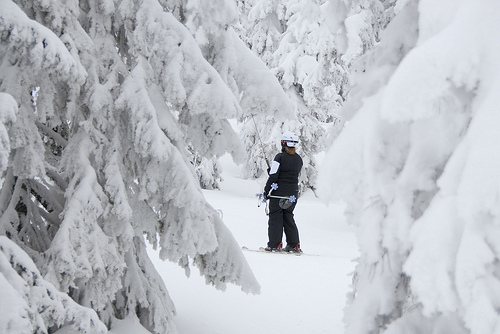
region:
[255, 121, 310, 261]
man with goggles on back of head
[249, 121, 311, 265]
person with goggles on back of head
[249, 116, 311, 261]
guy with goggles on back of head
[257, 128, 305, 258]
man with goggles on head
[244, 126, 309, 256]
person with goggles on head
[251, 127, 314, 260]
guy with goggles on head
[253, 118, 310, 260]
man standing on snow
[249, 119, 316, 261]
man in white hat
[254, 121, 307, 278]
person in white hat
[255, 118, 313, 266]
guy in white hat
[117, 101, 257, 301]
Snow-covered evergreen branch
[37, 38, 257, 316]
Snow-covered trees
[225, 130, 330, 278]
Cross-country skier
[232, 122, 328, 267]
Cross-country skier not using his poles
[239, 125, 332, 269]
Cross-country skier in the snow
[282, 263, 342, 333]
Snow on the ground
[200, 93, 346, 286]
Cross-country skier in the forest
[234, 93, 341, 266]
Cross-country skier in the snow-covered forest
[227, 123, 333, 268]
Cross-country skier taking in the scenery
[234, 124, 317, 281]
Snow skier taking a break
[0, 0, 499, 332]
the trees are heavy with snow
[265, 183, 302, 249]
the girl is wearing black pants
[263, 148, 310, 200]
the girl is wearing a black jacket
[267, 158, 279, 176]
the jacket has white patches on the sleeves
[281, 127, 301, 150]
the girl is wearing a white helmet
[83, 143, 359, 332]
the snow is on the ground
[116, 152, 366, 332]
the snow on the ground is white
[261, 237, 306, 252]
the girl is wearing black boots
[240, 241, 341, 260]
the girl is wearing skis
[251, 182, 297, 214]
the girl is carrying ski poles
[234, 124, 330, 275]
person on some skis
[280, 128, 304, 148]
a white plastic helmet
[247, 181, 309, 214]
pair of ski poles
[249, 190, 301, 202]
silver metal ski pole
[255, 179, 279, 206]
silver metal ski pole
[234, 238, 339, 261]
pair of white skis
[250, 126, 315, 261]
person wearing black coat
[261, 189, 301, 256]
pair of black snow pants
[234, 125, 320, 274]
person wearing helmet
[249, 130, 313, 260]
person standing on skis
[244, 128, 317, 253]
person skiing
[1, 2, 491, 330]
heavy white snow clinging to tree branches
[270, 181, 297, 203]
blue baskets on the ends of ski poles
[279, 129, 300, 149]
person wearing a white helmet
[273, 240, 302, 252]
red bindings on skis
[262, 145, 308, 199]
person in a black jacket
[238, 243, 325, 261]
skis covered in snow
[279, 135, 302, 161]
skier with brown hair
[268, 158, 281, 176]
white arm patch on a black jacket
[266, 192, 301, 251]
person wearing black snow pants